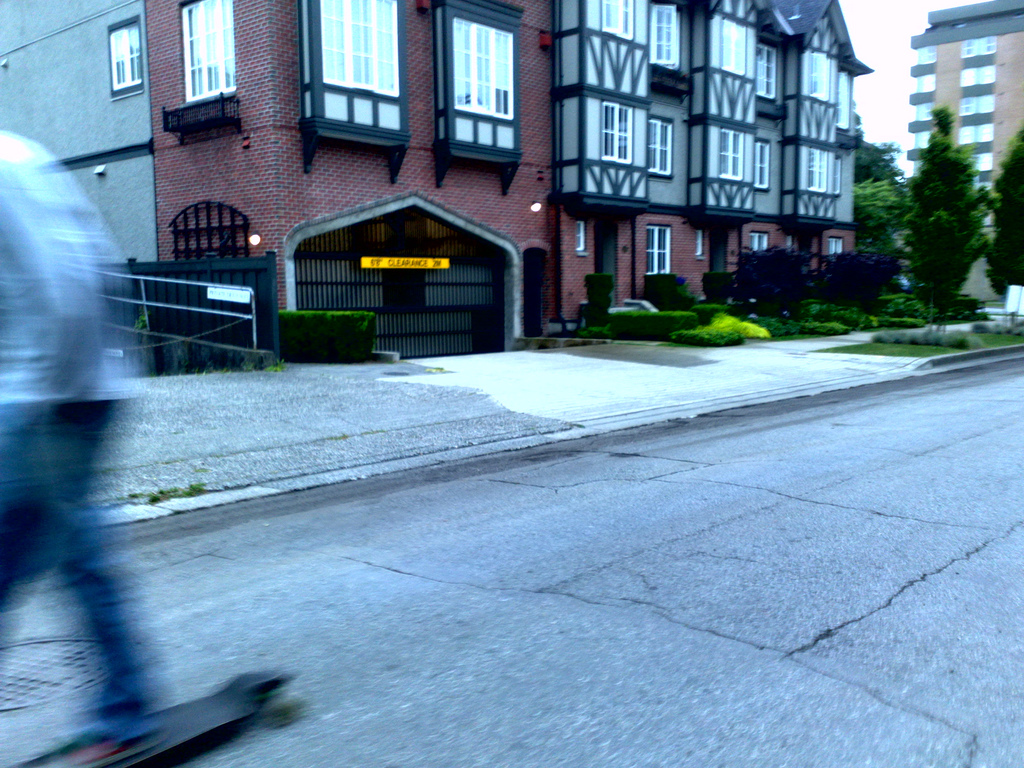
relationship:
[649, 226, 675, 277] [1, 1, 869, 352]
window on building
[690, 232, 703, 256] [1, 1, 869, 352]
window on building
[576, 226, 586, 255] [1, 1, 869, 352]
window on building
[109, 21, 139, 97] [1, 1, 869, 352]
window on building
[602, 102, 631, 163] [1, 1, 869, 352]
window on building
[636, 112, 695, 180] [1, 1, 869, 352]
window on building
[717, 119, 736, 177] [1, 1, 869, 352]
window on building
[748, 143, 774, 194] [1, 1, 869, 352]
window on building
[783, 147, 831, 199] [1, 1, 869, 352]
window on building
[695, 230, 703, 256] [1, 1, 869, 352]
window on building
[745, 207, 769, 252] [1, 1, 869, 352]
window on building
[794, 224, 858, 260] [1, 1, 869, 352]
window on building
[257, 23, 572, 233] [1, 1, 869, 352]
wall on building